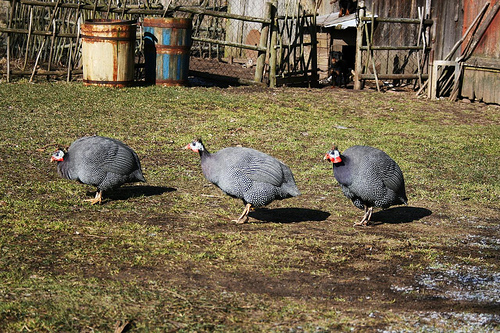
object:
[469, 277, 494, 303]
cereals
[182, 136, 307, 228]
person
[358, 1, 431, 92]
fence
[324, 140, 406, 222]
guinea hen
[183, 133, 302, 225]
guinea hen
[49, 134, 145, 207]
guinea hen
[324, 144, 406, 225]
ginney chicken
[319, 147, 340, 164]
face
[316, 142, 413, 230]
birds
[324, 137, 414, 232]
turkeys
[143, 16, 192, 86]
barrel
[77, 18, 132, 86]
barrel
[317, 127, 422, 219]
turkey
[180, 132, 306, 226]
turkey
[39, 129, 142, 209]
turkey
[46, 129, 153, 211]
turkeys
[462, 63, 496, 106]
wood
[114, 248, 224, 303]
ground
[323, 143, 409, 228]
guinea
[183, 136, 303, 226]
guinea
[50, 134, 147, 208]
guinea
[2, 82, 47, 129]
grass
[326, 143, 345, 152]
knob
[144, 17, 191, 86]
trash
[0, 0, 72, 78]
fence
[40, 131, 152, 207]
bird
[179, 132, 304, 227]
bird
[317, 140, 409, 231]
bird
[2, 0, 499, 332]
turkey farm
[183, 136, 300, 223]
turkey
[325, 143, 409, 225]
turkey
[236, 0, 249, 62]
poles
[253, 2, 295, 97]
wood post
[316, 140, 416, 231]
hen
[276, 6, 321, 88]
gate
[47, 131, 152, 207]
birds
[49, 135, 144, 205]
turkey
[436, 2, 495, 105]
building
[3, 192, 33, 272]
grass